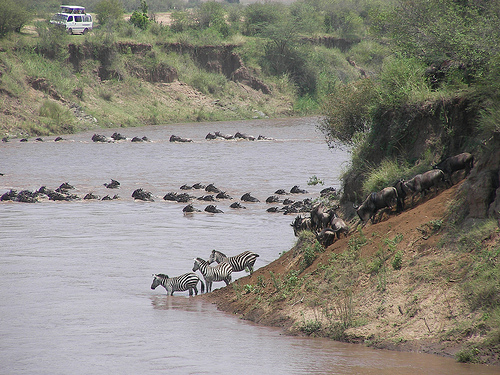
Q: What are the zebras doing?
A: Going in water.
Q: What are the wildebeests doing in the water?
A: Swimming.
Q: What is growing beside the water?
A: Grass.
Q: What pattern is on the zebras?
A: Stripes.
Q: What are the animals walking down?
A: Cliff.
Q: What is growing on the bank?
A: Grass.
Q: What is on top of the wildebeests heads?
A: Horns.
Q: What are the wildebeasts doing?
A: Crossing.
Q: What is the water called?
A: River.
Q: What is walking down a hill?
A: Several water buffalos.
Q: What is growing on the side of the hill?
A: Plants.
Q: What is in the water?
A: Many water buffalo.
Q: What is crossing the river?
A: Several water buffalo.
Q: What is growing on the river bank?
A: Several trees.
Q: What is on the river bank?
A: Dirt cliff face.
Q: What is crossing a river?
A: Wildebeest.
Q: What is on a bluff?
A: Shrubs.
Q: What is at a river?
A: Wild animals.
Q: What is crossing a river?
A: Animals.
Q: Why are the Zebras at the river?
A: They are drinking.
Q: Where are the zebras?
A: By the water.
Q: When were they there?
A: During the day.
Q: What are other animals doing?
A: Standing in the water.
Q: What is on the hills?
A: PLants and grass.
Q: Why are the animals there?
A: To eat and drink.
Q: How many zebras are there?
A: Three.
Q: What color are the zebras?
A: Black and white.